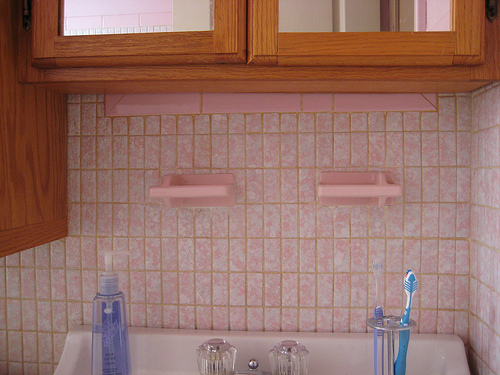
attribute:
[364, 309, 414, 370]
holder — chrome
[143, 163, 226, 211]
soap — pink, dispenser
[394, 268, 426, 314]
toothbrush — blue, metal, holder, purple, chrome, clear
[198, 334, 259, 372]
knob — water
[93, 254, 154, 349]
soap — bottle, hand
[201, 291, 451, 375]
sink — white, bathroom, clear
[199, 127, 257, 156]
tile — pink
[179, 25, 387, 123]
cabinet — wooden, door, bathroom, medicine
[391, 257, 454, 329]
brush — head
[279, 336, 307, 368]
handle — tap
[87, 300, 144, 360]
bottle — clear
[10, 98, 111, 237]
cup — board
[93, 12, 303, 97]
cupboard — glass, wood, bathroom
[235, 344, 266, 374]
tap — water